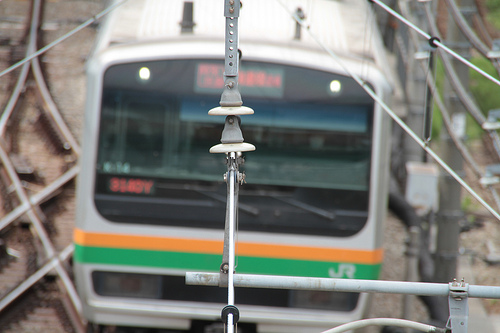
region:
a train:
[87, 39, 456, 281]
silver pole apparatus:
[204, 2, 276, 331]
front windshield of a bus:
[90, 30, 369, 256]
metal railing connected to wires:
[178, 247, 496, 327]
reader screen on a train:
[97, 170, 152, 205]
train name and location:
[185, 55, 290, 100]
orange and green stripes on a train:
[75, 216, 405, 301]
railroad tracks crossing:
[0, 5, 95, 330]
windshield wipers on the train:
[160, 165, 343, 236]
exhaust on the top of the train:
[290, 3, 315, 48]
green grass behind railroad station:
[440, 32, 498, 113]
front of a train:
[36, 22, 401, 331]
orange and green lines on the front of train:
[43, 219, 382, 291]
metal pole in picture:
[191, 260, 482, 325]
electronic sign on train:
[191, 42, 301, 99]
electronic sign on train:
[84, 156, 176, 203]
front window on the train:
[96, 21, 381, 246]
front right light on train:
[313, 54, 374, 113]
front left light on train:
[111, 50, 185, 88]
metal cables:
[282, 16, 478, 156]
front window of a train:
[308, 120, 333, 156]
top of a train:
[324, 36, 331, 53]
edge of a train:
[75, 210, 135, 227]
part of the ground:
[473, 48, 480, 72]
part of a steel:
[418, 282, 433, 288]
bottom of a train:
[164, 279, 167, 303]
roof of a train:
[261, 27, 276, 39]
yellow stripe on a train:
[172, 248, 189, 257]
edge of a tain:
[446, 174, 456, 191]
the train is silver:
[61, 3, 423, 329]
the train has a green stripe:
[49, 191, 410, 291]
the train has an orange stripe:
[59, 206, 389, 303]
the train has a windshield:
[91, 42, 401, 264]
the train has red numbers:
[100, 158, 166, 214]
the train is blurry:
[63, 7, 420, 332]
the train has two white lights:
[126, 43, 353, 114]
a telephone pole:
[406, 1, 496, 324]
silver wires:
[266, 1, 493, 234]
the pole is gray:
[179, 253, 497, 313]